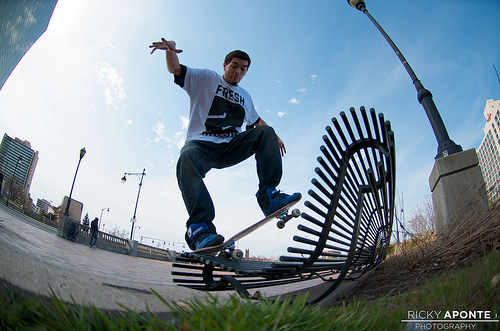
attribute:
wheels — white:
[270, 208, 302, 228]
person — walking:
[87, 214, 102, 246]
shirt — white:
[165, 40, 292, 167]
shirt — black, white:
[166, 60, 248, 139]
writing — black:
[217, 80, 247, 100]